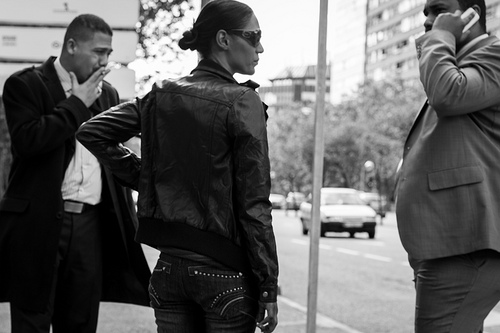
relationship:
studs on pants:
[154, 259, 245, 307] [149, 249, 266, 332]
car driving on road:
[304, 195, 373, 236] [253, 195, 499, 331]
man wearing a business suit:
[385, 5, 500, 332] [404, 34, 492, 333]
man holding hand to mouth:
[395, 0, 500, 333] [93, 60, 106, 82]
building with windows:
[358, 7, 499, 168] [366, 7, 433, 98]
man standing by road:
[395, 0, 500, 333] [253, 195, 499, 331]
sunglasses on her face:
[232, 29, 265, 44] [227, 18, 266, 73]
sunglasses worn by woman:
[232, 29, 265, 44] [79, 1, 296, 333]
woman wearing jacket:
[79, 1, 296, 333] [82, 88, 286, 287]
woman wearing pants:
[79, 1, 296, 333] [149, 249, 266, 332]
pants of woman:
[149, 249, 266, 332] [79, 1, 296, 333]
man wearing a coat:
[395, 0, 500, 333] [4, 62, 150, 308]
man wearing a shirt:
[395, 0, 500, 333] [56, 64, 98, 206]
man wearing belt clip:
[395, 0, 500, 333] [61, 203, 87, 218]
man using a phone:
[385, 5, 500, 332] [458, 7, 477, 33]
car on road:
[304, 195, 373, 236] [253, 195, 499, 331]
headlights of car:
[325, 216, 376, 226] [304, 195, 373, 236]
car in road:
[304, 195, 373, 236] [253, 195, 499, 331]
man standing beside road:
[385, 5, 500, 332] [253, 195, 499, 331]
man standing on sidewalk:
[395, 0, 500, 333] [5, 237, 347, 332]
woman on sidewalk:
[79, 1, 296, 333] [5, 237, 347, 332]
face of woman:
[227, 18, 266, 73] [79, 1, 296, 333]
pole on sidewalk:
[303, 3, 340, 333] [5, 237, 347, 332]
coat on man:
[4, 62, 150, 308] [395, 0, 500, 333]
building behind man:
[358, 0, 500, 206] [395, 0, 500, 333]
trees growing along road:
[264, 81, 422, 199] [253, 195, 499, 331]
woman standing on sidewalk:
[79, 1, 296, 333] [5, 237, 347, 332]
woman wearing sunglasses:
[79, 1, 296, 333] [232, 29, 265, 44]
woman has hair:
[79, 1, 296, 333] [175, 2, 246, 55]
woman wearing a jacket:
[79, 1, 296, 333] [82, 88, 286, 287]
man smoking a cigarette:
[395, 0, 500, 333] [101, 70, 109, 81]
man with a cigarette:
[395, 0, 500, 333] [101, 70, 109, 81]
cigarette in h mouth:
[101, 70, 109, 81] [93, 60, 106, 82]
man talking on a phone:
[385, 5, 500, 332] [458, 7, 477, 33]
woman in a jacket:
[79, 1, 296, 333] [82, 88, 286, 287]